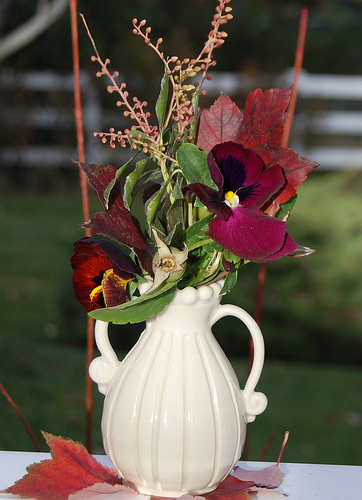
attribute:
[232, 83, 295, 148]
flower — beautiful 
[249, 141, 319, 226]
flower — beautiful 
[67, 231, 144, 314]
flower — beautiful 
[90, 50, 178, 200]
flower — beautiful 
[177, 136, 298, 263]
flower — beautiful 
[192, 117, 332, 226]
flower — purple 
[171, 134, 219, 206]
leaf — red, yellow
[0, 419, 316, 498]
leaves — cranberry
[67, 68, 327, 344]
leaves — cranberry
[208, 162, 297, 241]
flower — tiny, yellow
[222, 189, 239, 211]
center — white, yellow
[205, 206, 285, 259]
petal — purple 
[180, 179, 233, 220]
petal — purple 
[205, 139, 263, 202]
petal — purple 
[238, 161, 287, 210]
petal — purple 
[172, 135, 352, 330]
flower — pink , purple 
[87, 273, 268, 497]
vase — white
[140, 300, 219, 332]
short neck —  short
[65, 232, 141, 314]
red flower — dark, yellow edged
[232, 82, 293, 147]
leaf — red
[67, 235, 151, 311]
flower — red , yellow 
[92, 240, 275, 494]
vase — white 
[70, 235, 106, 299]
petals — dark , red 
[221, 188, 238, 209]
center — yellow , white 